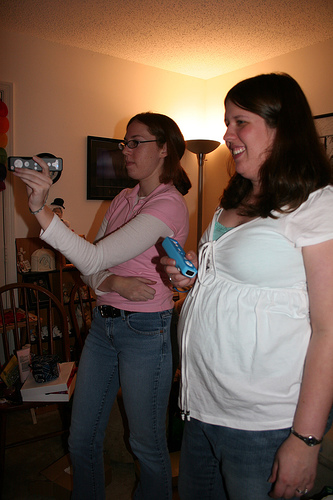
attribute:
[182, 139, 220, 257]
floor lamp — on, illuminating, tall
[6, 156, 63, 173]
wiimote — black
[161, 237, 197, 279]
wiimote — blue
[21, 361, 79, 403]
cardboard box — white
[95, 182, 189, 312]
shirt — pink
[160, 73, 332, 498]
woman — pregnant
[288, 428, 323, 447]
watch — silver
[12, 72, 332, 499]
women — playing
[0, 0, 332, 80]
ceiling — white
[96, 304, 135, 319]
belt — black